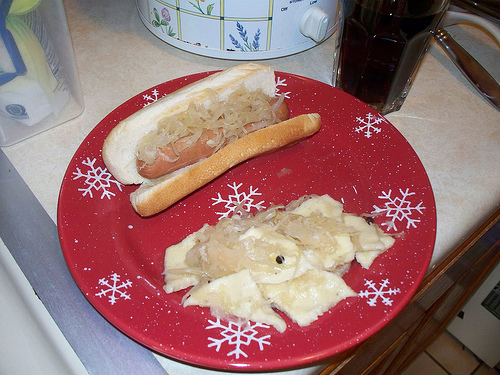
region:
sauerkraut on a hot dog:
[52, 67, 344, 215]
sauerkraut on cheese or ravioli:
[156, 199, 378, 332]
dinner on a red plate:
[51, 67, 411, 362]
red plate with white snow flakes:
[45, 35, 416, 365]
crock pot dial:
[165, 5, 340, 75]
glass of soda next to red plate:
[317, 1, 432, 141]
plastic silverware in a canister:
[2, 1, 103, 156]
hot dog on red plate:
[75, 83, 397, 353]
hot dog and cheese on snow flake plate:
[45, 50, 420, 350]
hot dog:
[101, 109, 311, 174]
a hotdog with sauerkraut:
[97, 64, 319, 216]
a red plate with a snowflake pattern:
[58, 66, 438, 373]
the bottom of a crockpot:
[135, 1, 340, 60]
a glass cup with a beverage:
[334, 0, 449, 115]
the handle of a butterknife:
[434, 25, 499, 116]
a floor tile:
[420, 329, 485, 374]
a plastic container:
[0, 0, 86, 148]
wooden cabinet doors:
[321, 210, 498, 372]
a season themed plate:
[56, 63, 437, 370]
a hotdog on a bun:
[102, 62, 321, 216]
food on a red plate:
[55, 69, 427, 338]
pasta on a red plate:
[173, 202, 388, 290]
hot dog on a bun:
[87, 129, 340, 206]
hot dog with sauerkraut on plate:
[85, 71, 309, 199]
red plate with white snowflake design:
[344, 117, 439, 230]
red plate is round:
[18, 121, 169, 356]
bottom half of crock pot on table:
[145, 0, 337, 70]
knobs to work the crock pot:
[264, 0, 326, 74]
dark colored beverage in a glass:
[323, 0, 450, 134]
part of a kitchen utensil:
[390, 7, 490, 133]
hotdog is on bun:
[102, 61, 327, 209]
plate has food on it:
[105, 63, 423, 320]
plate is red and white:
[60, 67, 437, 370]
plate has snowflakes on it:
[212, 183, 273, 227]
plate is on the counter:
[396, 112, 493, 289]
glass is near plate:
[340, 15, 440, 120]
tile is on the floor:
[412, 335, 488, 374]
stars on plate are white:
[73, 158, 130, 211]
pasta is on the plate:
[158, 193, 394, 330]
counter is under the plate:
[20, 39, 499, 370]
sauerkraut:
[117, 91, 314, 138]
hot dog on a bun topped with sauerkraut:
[98, 89, 313, 174]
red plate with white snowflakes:
[307, 65, 419, 360]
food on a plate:
[154, 195, 396, 312]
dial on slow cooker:
[279, 0, 334, 61]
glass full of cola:
[325, 0, 444, 138]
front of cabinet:
[391, 256, 479, 361]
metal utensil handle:
[431, 11, 496, 119]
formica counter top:
[403, 55, 490, 190]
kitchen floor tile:
[408, 313, 484, 370]